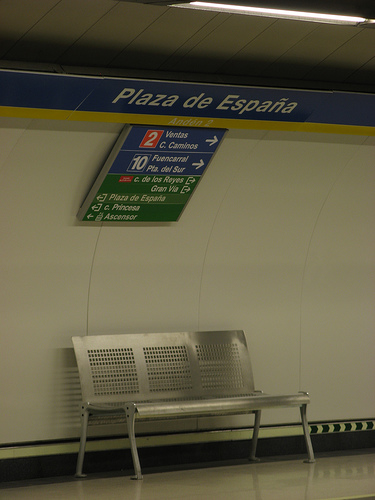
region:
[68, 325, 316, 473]
a wire mesh bench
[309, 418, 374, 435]
arrows on the wall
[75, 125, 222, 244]
a sign giving directions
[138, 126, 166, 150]
white two on red square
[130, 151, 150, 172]
white ten on blue square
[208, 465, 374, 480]
reflection of arrows on floor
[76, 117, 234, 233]
a blue and green sign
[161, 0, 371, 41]
long flourescent light fixture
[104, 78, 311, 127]
sign on the wall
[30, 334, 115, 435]
shadow of bench on wall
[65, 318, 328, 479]
a cold metal bench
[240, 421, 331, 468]
bench legs bolted to the ground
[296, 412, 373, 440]
green chevron pattern on wall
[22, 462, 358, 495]
pale and shiny floor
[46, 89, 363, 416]
a white curved wall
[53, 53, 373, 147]
a long blue and yellow sign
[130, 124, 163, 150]
number 2 in a red box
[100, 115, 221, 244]
blue and green rectangular sign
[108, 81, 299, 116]
spanish in white writing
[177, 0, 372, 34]
ceiling light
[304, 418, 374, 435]
Black and white arrows on the molding on the wall beside the bench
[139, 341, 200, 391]
Middle section of holes in the back of the bench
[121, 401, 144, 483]
Front leg of the bench on the left hand side of the photo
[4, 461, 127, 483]
Thick black strip at the bottom of the wall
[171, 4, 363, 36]
Light in the ceiling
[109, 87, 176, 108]
The word 'Plaza' in the blue part of the sign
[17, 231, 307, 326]
Empty expanse of wall between the bench and the sign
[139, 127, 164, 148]
Red number '2' on the sign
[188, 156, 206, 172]
Second white arrow from the top on the sign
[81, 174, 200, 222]
Green portion of the sign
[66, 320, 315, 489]
metal bench in underground station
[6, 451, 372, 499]
waxed reflective tiled floor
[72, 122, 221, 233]
informational sign with directional arrows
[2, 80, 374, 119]
long blue sign for Plaza de Espana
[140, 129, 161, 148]
white 2 on a red square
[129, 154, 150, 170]
white 10 on a blue square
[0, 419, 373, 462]
railing running along bottom of wall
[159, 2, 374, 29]
fluorescent tube lighting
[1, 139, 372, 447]
white curving tunnel wall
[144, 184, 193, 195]
sign reading Gran Via with a right pointing arrow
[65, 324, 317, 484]
the bench is made of metal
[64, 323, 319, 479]
the bench is shiny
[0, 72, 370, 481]
the wall goes up into a curve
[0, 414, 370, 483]
the wall has black trim next to the floor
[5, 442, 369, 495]
the floor is white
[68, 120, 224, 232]
the sign above the bench is green and white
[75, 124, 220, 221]
the sign above the bench has white writing on it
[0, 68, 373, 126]
the top of the wall has a blue stripe painted on it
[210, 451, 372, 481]
the black trim next to the floor is reflecting on the linolium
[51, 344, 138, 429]
the shadow of the bench is on the wall